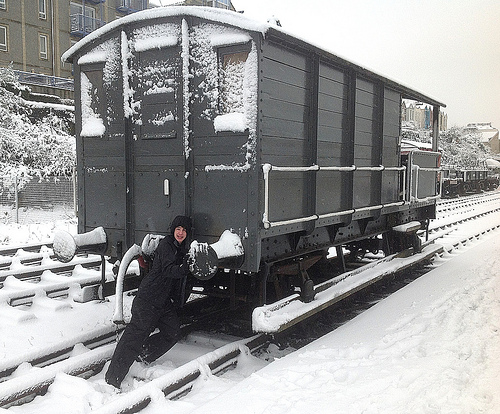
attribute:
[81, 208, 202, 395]
person — leaning, pushing, dressed, pretending, young, trying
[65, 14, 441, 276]
train — parked, covered, green, pushed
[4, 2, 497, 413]
photo — black, white, color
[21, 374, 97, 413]
snow — piled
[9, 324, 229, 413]
tracks — covered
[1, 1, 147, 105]
building — olive, brick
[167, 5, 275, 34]
snow — powdery, white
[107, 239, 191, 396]
snow suit — black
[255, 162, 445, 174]
rails — silver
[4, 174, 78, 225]
fence — surrounding, metal, silver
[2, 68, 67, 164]
tree — covered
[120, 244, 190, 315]
coat — black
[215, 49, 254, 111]
window — glass